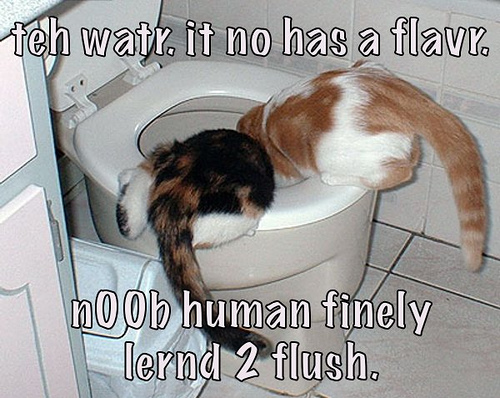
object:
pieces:
[67, 73, 86, 95]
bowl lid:
[41, 0, 158, 114]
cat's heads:
[78, 55, 498, 355]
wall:
[167, 0, 500, 262]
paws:
[316, 163, 415, 190]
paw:
[115, 182, 149, 242]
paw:
[194, 212, 251, 250]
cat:
[113, 129, 276, 357]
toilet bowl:
[81, 61, 378, 387]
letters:
[68, 288, 433, 381]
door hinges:
[44, 202, 66, 263]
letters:
[11, 15, 490, 59]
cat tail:
[155, 192, 272, 361]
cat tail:
[382, 93, 489, 273]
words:
[7, 10, 496, 65]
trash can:
[60, 229, 214, 398]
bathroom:
[0, 0, 500, 398]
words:
[69, 287, 433, 382]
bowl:
[76, 56, 379, 232]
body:
[117, 129, 269, 252]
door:
[0, 28, 94, 398]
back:
[119, 127, 272, 222]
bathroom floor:
[194, 217, 499, 398]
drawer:
[0, 36, 42, 187]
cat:
[236, 61, 486, 276]